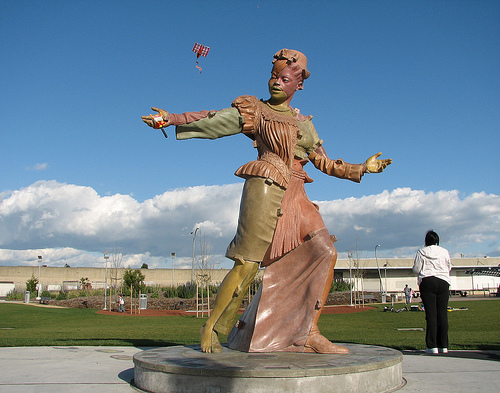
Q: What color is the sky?
A: Blue.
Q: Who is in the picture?
A: A woman.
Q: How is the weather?
A: Clear.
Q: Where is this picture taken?
A: A park.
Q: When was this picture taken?
A: Daytime.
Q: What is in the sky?
A: A kite.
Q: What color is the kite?
A: Red.